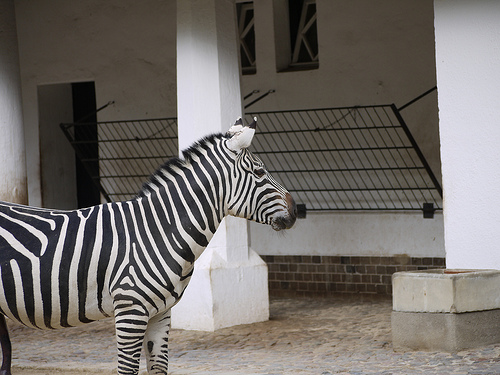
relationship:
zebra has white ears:
[3, 110, 309, 375] [220, 110, 259, 154]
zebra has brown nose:
[3, 110, 309, 375] [282, 191, 302, 225]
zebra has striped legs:
[3, 110, 309, 375] [111, 297, 175, 375]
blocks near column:
[385, 263, 499, 318] [426, 1, 499, 271]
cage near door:
[60, 89, 451, 227] [33, 73, 106, 208]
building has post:
[8, 1, 499, 334] [163, 1, 272, 336]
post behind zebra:
[163, 1, 272, 336] [3, 110, 309, 375]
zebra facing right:
[3, 110, 309, 375] [426, 1, 499, 271]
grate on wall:
[60, 89, 451, 227] [16, 9, 443, 267]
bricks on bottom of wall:
[263, 253, 448, 302] [16, 9, 443, 267]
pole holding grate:
[400, 85, 438, 111] [60, 89, 451, 227]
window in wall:
[269, 1, 326, 79] [16, 9, 443, 267]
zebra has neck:
[3, 110, 309, 375] [136, 141, 227, 259]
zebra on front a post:
[3, 110, 309, 375] [163, 1, 272, 336]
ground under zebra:
[14, 327, 499, 372] [3, 110, 309, 375]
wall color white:
[16, 9, 443, 267] [8, 1, 499, 334]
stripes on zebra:
[61, 218, 182, 270] [3, 110, 309, 375]